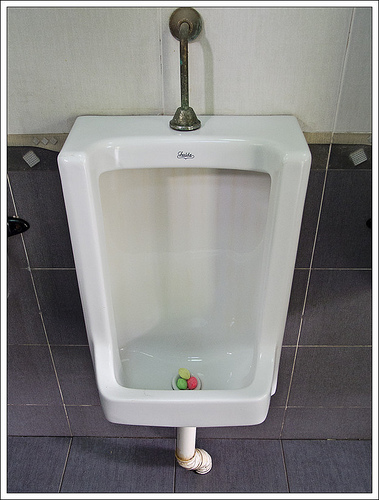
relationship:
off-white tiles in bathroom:
[11, 4, 370, 114] [18, 26, 352, 451]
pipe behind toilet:
[172, 425, 218, 476] [57, 114, 310, 425]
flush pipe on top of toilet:
[164, 8, 213, 135] [57, 114, 312, 474]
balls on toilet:
[143, 361, 211, 395] [40, 94, 307, 409]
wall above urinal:
[201, 10, 370, 113] [54, 109, 320, 428]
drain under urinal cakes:
[169, 365, 213, 476] [178, 369, 190, 379]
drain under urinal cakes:
[169, 365, 213, 476] [186, 374, 197, 389]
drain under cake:
[169, 365, 213, 476] [174, 376, 186, 387]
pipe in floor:
[172, 425, 218, 476] [10, 427, 368, 489]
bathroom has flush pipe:
[56, 8, 313, 476] [164, 8, 213, 135]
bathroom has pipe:
[56, 8, 313, 476] [172, 425, 218, 476]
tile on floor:
[281, 438, 371, 492] [10, 427, 368, 489]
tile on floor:
[174, 438, 288, 493] [10, 427, 368, 489]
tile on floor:
[60, 434, 176, 491] [10, 427, 368, 489]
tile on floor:
[7, 435, 71, 490] [10, 427, 368, 489]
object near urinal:
[7, 214, 30, 239] [54, 109, 320, 428]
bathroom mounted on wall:
[56, 8, 313, 476] [11, 58, 359, 459]